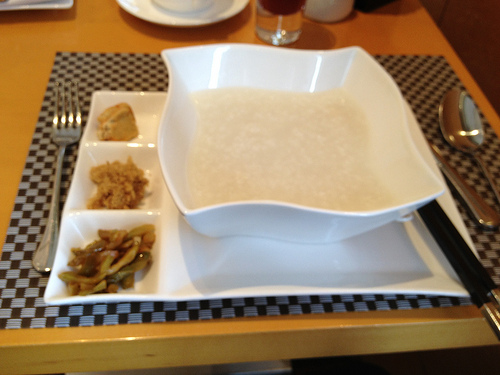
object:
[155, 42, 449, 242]
bowl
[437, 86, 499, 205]
spoon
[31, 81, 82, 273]
fork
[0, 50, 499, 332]
placemat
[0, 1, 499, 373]
table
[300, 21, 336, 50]
shadow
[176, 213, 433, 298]
shadow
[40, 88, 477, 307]
plate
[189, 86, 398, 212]
soup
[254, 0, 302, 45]
glass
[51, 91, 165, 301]
sections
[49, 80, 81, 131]
tines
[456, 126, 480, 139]
light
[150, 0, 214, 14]
mug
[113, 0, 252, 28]
saucer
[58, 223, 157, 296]
beans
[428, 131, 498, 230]
knife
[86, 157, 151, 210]
ginger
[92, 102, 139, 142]
food